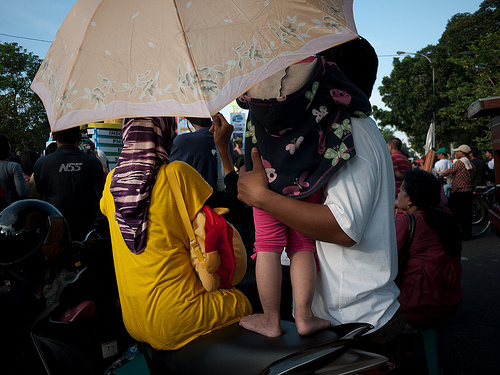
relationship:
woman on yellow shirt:
[98, 117, 253, 352] [92, 162, 250, 345]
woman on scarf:
[98, 117, 253, 352] [109, 115, 176, 253]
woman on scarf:
[98, 117, 253, 352] [95, 115, 178, 257]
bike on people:
[7, 172, 118, 373] [16, 26, 498, 361]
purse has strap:
[186, 239, 231, 289] [164, 171, 199, 256]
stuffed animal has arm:
[191, 197, 249, 297] [200, 221, 221, 274]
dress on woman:
[96, 157, 254, 354] [61, 138, 264, 356]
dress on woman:
[396, 209, 453, 325] [396, 174, 453, 334]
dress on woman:
[99, 160, 252, 350] [98, 117, 253, 352]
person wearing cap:
[433, 144, 473, 241] [452, 141, 469, 152]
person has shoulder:
[431, 131, 485, 242] [453, 160, 463, 169]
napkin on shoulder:
[457, 155, 474, 172] [453, 160, 463, 169]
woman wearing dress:
[98, 117, 253, 352] [96, 157, 254, 354]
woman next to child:
[98, 117, 253, 352] [235, 56, 372, 317]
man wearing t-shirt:
[234, 35, 345, 348] [307, 112, 403, 338]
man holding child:
[234, 35, 345, 348] [235, 56, 372, 317]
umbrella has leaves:
[25, 0, 362, 134] [175, 62, 225, 94]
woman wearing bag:
[98, 117, 253, 352] [160, 155, 252, 285]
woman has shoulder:
[98, 117, 253, 352] [154, 152, 207, 182]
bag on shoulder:
[160, 155, 252, 285] [154, 152, 207, 182]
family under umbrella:
[91, 83, 442, 339] [18, 0, 412, 131]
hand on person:
[214, 157, 289, 222] [191, 79, 429, 276]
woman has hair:
[88, 126, 248, 330] [109, 118, 175, 254]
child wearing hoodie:
[237, 48, 356, 336] [236, 85, 363, 188]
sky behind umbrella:
[368, 17, 452, 53] [25, 0, 362, 134]